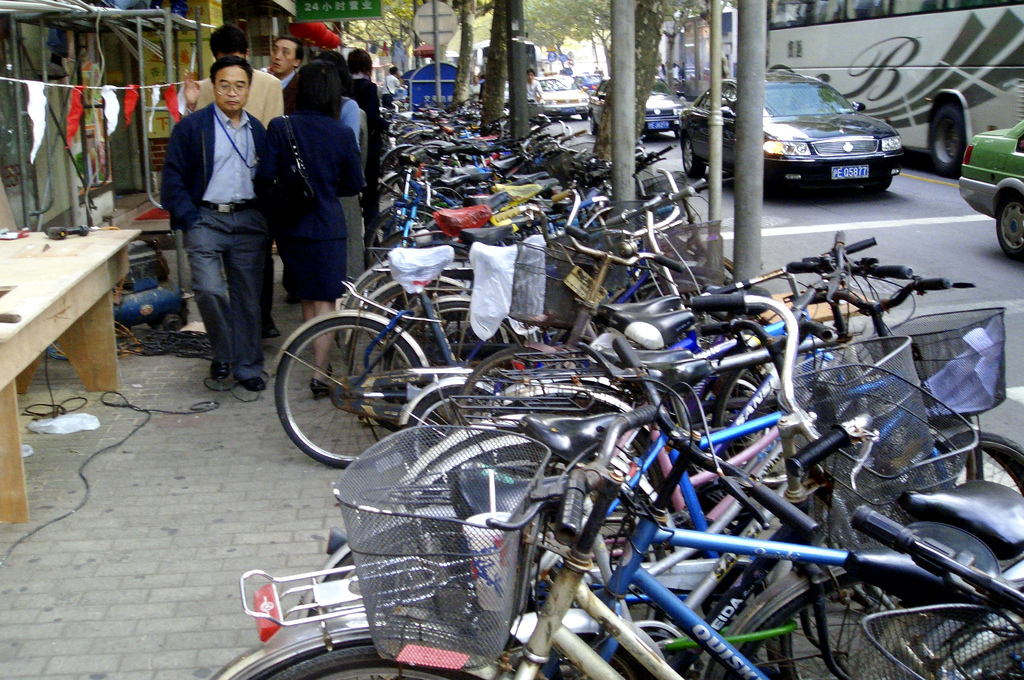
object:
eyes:
[224, 84, 244, 89]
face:
[216, 66, 249, 111]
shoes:
[210, 359, 267, 392]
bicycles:
[214, 71, 1013, 677]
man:
[162, 56, 271, 393]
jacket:
[161, 101, 271, 230]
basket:
[336, 422, 550, 668]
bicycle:
[525, 401, 1010, 676]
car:
[674, 72, 901, 200]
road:
[641, 128, 1024, 443]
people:
[161, 58, 364, 400]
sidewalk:
[0, 315, 444, 675]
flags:
[13, 82, 186, 149]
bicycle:
[194, 395, 988, 679]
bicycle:
[339, 232, 1024, 678]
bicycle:
[210, 227, 1024, 680]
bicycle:
[273, 192, 717, 469]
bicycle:
[273, 181, 765, 468]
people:
[161, 55, 270, 397]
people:
[269, 59, 368, 401]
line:
[214, 60, 1003, 676]